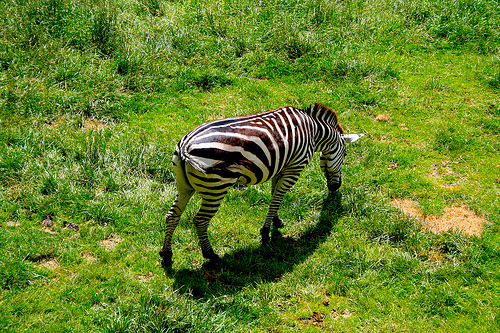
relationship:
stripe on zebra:
[223, 136, 256, 151] [144, 89, 371, 281]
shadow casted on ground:
[170, 189, 344, 305] [2, 1, 484, 329]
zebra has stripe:
[155, 97, 363, 281] [188, 133, 274, 172]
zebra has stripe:
[155, 100, 366, 275] [229, 125, 299, 141]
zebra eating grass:
[155, 100, 366, 275] [9, 7, 480, 324]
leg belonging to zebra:
[256, 171, 304, 232] [155, 100, 366, 275]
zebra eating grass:
[155, 100, 366, 275] [324, 180, 356, 207]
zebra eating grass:
[155, 97, 363, 281] [303, 180, 400, 241]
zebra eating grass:
[155, 100, 366, 275] [299, 182, 386, 222]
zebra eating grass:
[155, 100, 366, 275] [296, 187, 376, 219]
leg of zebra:
[192, 187, 223, 267] [155, 100, 366, 275]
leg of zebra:
[256, 160, 309, 240] [155, 100, 366, 275]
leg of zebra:
[159, 190, 184, 267] [155, 97, 363, 281]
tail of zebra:
[171, 138, 207, 189] [155, 100, 366, 275]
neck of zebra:
[307, 110, 334, 153] [155, 97, 363, 281]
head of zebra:
[318, 127, 351, 194] [155, 100, 366, 275]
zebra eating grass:
[155, 100, 366, 275] [301, 186, 408, 284]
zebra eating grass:
[155, 100, 366, 275] [295, 174, 405, 295]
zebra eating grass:
[155, 100, 366, 275] [307, 186, 414, 292]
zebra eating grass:
[155, 97, 363, 281] [43, 42, 163, 199]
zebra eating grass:
[155, 100, 366, 275] [297, 188, 407, 331]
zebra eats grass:
[155, 97, 363, 281] [239, 25, 488, 279]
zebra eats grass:
[155, 97, 363, 281] [157, 29, 427, 303]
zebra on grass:
[155, 97, 363, 281] [308, 174, 391, 237]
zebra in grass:
[155, 97, 363, 281] [104, 47, 414, 301]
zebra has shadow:
[155, 97, 363, 281] [173, 194, 351, 306]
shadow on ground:
[168, 189, 344, 305] [135, 56, 389, 326]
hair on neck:
[295, 96, 347, 130] [312, 118, 335, 154]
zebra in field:
[155, 97, 363, 281] [108, 49, 409, 307]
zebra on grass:
[155, 97, 363, 281] [104, 47, 414, 301]